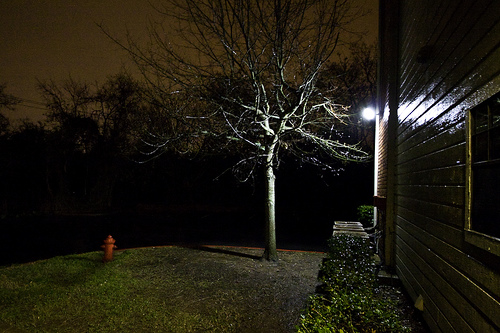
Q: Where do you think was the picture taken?
A: It was taken at the yard.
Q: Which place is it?
A: It is a yard.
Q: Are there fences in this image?
A: No, there are no fences.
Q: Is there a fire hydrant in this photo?
A: Yes, there is a fire hydrant.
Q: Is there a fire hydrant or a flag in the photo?
A: Yes, there is a fire hydrant.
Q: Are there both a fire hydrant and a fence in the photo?
A: No, there is a fire hydrant but no fences.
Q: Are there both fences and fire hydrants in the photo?
A: No, there is a fire hydrant but no fences.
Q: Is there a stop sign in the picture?
A: No, there are no stop signs.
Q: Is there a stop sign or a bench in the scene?
A: No, there are no stop signs or benches.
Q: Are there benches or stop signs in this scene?
A: No, there are no stop signs or benches.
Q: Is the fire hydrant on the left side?
A: Yes, the fire hydrant is on the left of the image.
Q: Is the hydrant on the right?
A: No, the hydrant is on the left of the image.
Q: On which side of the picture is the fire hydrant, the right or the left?
A: The fire hydrant is on the left of the image.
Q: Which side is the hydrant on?
A: The hydrant is on the left of the image.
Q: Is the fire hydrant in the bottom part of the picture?
A: Yes, the fire hydrant is in the bottom of the image.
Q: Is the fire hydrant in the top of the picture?
A: No, the fire hydrant is in the bottom of the image.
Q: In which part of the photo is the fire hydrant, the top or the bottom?
A: The fire hydrant is in the bottom of the image.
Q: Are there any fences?
A: No, there are no fences.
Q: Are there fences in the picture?
A: No, there are no fences.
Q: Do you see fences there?
A: No, there are no fences.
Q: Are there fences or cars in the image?
A: No, there are no fences or cars.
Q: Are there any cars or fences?
A: No, there are no fences or cars.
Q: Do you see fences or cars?
A: No, there are no fences or cars.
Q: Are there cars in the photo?
A: No, there are no cars.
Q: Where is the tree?
A: The tree is in the yard.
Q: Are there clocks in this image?
A: No, there are no clocks.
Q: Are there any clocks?
A: No, there are no clocks.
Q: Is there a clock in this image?
A: No, there are no clocks.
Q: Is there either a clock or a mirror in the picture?
A: No, there are no clocks or mirrors.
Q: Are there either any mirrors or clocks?
A: No, there are no clocks or mirrors.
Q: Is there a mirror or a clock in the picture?
A: No, there are no clocks or mirrors.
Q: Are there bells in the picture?
A: No, there are no bells.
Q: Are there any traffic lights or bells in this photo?
A: No, there are no bells or traffic lights.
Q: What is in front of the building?
A: The bushes are in front of the building.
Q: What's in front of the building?
A: The bushes are in front of the building.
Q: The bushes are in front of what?
A: The bushes are in front of the building.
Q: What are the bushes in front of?
A: The bushes are in front of the building.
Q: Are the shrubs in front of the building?
A: Yes, the shrubs are in front of the building.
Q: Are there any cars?
A: No, there are no cars.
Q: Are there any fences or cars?
A: No, there are no cars or fences.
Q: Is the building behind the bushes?
A: Yes, the building is behind the bushes.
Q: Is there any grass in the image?
A: Yes, there is grass.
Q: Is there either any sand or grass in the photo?
A: Yes, there is grass.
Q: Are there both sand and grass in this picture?
A: No, there is grass but no sand.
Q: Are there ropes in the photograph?
A: No, there are no ropes.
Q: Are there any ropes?
A: No, there are no ropes.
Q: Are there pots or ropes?
A: No, there are no ropes or pots.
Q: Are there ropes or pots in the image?
A: No, there are no ropes or pots.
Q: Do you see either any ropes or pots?
A: No, there are no ropes or pots.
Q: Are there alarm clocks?
A: No, there are no alarm clocks.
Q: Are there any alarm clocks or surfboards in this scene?
A: No, there are no alarm clocks or surfboards.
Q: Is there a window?
A: Yes, there is a window.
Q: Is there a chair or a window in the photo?
A: Yes, there is a window.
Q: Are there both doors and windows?
A: No, there is a window but no doors.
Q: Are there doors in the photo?
A: No, there are no doors.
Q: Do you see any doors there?
A: No, there are no doors.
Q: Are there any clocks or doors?
A: No, there are no doors or clocks.